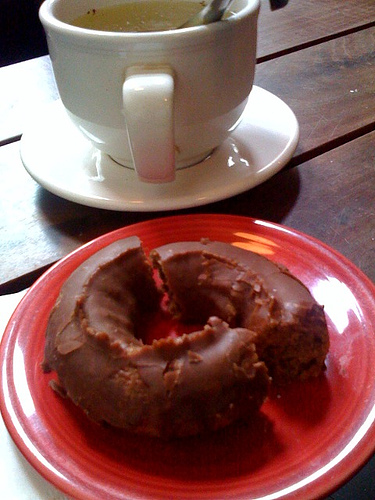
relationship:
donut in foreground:
[57, 246, 320, 458] [16, 67, 360, 493]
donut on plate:
[57, 246, 320, 458] [16, 67, 360, 493]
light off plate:
[221, 119, 261, 158] [0, 77, 322, 234]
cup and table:
[21, 8, 276, 206] [293, 72, 348, 106]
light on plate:
[221, 119, 261, 158] [0, 77, 322, 234]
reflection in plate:
[233, 136, 292, 187] [0, 77, 322, 234]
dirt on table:
[316, 68, 361, 101] [293, 72, 348, 106]